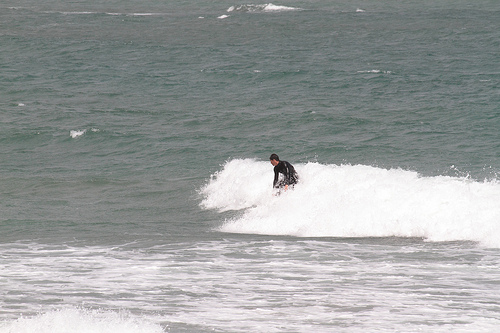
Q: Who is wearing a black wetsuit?
A: Surfer.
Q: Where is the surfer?
A: Ocean.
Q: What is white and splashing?
A: Caps of wave.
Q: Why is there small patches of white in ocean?
A: Small waves.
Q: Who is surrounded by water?
A: The man.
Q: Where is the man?
A: In the ocean.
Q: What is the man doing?
A: Surfing.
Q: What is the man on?
A: A wave.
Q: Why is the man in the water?
A: He is surfing.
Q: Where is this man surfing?
A: Perhaps in the ocean.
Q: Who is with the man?
A: He is alone.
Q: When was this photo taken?
A: During the daytime.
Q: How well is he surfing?
A: He is staying upright.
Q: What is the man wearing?
A: A wetsuit.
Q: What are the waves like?
A: They are choppy.